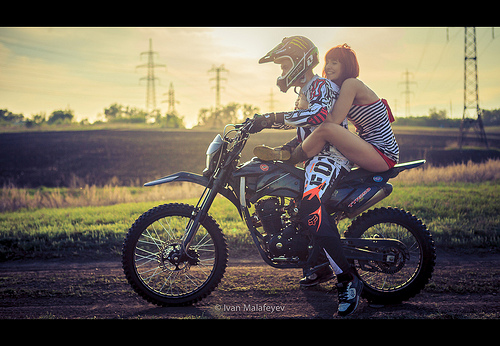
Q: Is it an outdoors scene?
A: Yes, it is outdoors.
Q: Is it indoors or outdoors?
A: It is outdoors.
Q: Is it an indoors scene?
A: No, it is outdoors.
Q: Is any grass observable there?
A: Yes, there is grass.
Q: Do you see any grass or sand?
A: Yes, there is grass.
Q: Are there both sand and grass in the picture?
A: No, there is grass but no sand.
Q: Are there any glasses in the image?
A: No, there are no glasses.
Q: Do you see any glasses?
A: No, there are no glasses.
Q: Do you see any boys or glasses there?
A: No, there are no glasses or boys.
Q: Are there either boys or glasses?
A: No, there are no glasses or boys.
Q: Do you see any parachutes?
A: No, there are no parachutes.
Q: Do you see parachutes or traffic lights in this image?
A: No, there are no parachutes or traffic lights.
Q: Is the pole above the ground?
A: Yes, the pole is above the ground.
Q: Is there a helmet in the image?
A: Yes, there is a helmet.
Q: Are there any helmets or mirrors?
A: Yes, there is a helmet.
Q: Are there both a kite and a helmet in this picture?
A: No, there is a helmet but no kites.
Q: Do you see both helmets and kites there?
A: No, there is a helmet but no kites.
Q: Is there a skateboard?
A: No, there are no skateboards.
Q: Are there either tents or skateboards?
A: No, there are no skateboards or tents.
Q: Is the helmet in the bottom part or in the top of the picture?
A: The helmet is in the top of the image.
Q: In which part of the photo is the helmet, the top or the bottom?
A: The helmet is in the top of the image.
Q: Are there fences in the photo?
A: No, there are no fences.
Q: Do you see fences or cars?
A: No, there are no fences or cars.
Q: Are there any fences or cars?
A: No, there are no fences or cars.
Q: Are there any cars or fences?
A: No, there are no fences or cars.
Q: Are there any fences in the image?
A: No, there are no fences.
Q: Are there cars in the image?
A: No, there are no cars.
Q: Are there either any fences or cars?
A: No, there are no cars or fences.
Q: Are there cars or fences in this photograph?
A: No, there are no cars or fences.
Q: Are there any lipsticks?
A: No, there are no lipsticks.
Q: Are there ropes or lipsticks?
A: No, there are no lipsticks or ropes.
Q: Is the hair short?
A: Yes, the hair is short.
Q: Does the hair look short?
A: Yes, the hair is short.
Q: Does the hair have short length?
A: Yes, the hair is short.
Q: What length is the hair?
A: The hair is short.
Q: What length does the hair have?
A: The hair has short length.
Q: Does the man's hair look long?
A: No, the hair is short.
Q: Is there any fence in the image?
A: No, there are no fences.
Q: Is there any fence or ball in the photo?
A: No, there are no fences or balls.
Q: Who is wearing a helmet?
A: The man is wearing a helmet.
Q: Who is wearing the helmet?
A: The man is wearing a helmet.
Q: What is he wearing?
A: The man is wearing a helmet.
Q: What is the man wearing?
A: The man is wearing a helmet.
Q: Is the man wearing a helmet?
A: Yes, the man is wearing a helmet.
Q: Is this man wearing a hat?
A: No, the man is wearing a helmet.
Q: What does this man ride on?
A: The man rides on a bike.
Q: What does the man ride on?
A: The man rides on a bike.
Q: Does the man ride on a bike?
A: Yes, the man rides on a bike.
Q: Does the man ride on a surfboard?
A: No, the man rides on a bike.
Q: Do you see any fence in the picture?
A: No, there are no fences.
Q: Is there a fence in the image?
A: No, there are no fences.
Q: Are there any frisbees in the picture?
A: No, there are no frisbees.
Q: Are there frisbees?
A: No, there are no frisbees.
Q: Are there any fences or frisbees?
A: No, there are no frisbees or fences.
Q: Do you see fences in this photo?
A: No, there are no fences.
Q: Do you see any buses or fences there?
A: No, there are no fences or buses.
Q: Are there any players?
A: No, there are no players.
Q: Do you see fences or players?
A: No, there are no players or fences.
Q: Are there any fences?
A: No, there are no fences.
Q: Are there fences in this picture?
A: No, there are no fences.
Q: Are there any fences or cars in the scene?
A: No, there are no fences or cars.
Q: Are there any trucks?
A: No, there are no trucks.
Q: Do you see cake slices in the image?
A: No, there are no cake slices.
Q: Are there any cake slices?
A: No, there are no cake slices.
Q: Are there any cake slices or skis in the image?
A: No, there are no cake slices or skis.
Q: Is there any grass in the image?
A: Yes, there is grass.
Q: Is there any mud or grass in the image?
A: Yes, there is grass.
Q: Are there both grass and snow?
A: No, there is grass but no snow.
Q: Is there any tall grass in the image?
A: Yes, there is tall grass.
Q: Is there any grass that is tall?
A: Yes, there is grass that is tall.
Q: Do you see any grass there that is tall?
A: Yes, there is grass that is tall.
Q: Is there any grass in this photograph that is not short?
A: Yes, there is tall grass.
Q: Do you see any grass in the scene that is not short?
A: Yes, there is tall grass.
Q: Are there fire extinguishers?
A: No, there are no fire extinguishers.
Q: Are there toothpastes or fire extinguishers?
A: No, there are no fire extinguishers or toothpastes.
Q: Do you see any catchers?
A: No, there are no catchers.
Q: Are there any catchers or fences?
A: No, there are no catchers or fences.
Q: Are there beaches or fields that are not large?
A: No, there is a field but it is large.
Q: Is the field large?
A: Yes, the field is large.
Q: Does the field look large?
A: Yes, the field is large.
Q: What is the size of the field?
A: The field is large.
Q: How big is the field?
A: The field is large.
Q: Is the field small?
A: No, the field is large.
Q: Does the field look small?
A: No, the field is large.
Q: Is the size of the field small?
A: No, the field is large.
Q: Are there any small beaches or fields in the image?
A: No, there is a field but it is large.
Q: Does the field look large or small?
A: The field is large.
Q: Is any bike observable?
A: Yes, there is a bike.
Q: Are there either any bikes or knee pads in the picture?
A: Yes, there is a bike.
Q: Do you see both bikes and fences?
A: No, there is a bike but no fences.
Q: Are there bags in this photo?
A: No, there are no bags.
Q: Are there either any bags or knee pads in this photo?
A: No, there are no bags or knee pads.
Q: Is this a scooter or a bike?
A: This is a bike.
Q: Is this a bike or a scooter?
A: This is a bike.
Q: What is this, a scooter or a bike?
A: This is a bike.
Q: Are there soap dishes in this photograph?
A: No, there are no soap dishes.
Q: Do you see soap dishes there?
A: No, there are no soap dishes.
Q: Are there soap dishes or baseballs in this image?
A: No, there are no soap dishes or baseballs.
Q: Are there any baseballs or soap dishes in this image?
A: No, there are no soap dishes or baseballs.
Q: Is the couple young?
A: Yes, the couple is young.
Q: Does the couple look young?
A: Yes, the couple is young.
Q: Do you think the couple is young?
A: Yes, the couple is young.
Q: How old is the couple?
A: The couple is young.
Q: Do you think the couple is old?
A: No, the couple is young.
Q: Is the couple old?
A: No, the couple is young.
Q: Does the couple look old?
A: No, the couple is young.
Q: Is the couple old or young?
A: The couple is young.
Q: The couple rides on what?
A: The couple rides on a bike.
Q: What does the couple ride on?
A: The couple rides on a bike.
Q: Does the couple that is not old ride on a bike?
A: Yes, the couple rides on a bike.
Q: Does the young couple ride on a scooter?
A: No, the couple rides on a bike.